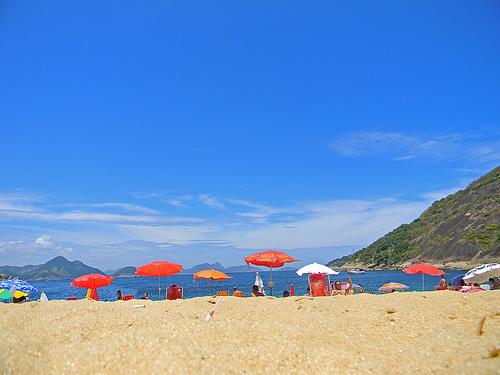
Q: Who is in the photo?
A: People sunbathing.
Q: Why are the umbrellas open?
A: Provide shade.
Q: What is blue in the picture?
A: The sky.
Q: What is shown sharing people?
A: Umbrellas.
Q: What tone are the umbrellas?
A: Orange and white.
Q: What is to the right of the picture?
A: Green mountain.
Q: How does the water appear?
A: Crisp, crystal blue.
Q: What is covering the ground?
A: Sand.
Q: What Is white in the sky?
A: Clouds.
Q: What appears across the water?
A: Hills.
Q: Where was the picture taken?
A: At a beach.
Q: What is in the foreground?
A: Sand.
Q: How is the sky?
A: Blue with a few clouds.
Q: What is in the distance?
A: Some mountains.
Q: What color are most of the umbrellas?
A: Orange.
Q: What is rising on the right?
A: A mountain side.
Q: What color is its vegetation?
A: Green.